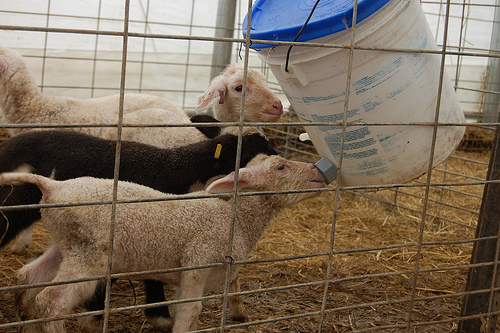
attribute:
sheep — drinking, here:
[0, 153, 328, 332]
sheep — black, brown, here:
[0, 113, 281, 252]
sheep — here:
[195, 64, 285, 141]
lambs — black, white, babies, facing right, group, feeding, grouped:
[0, 46, 326, 333]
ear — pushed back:
[204, 167, 256, 200]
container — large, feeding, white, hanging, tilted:
[242, 1, 467, 198]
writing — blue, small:
[289, 38, 427, 180]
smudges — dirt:
[339, 119, 466, 193]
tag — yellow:
[213, 142, 224, 160]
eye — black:
[275, 163, 286, 173]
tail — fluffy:
[0, 170, 52, 192]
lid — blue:
[242, 0, 391, 52]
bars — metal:
[1, 2, 499, 333]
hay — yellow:
[280, 209, 448, 290]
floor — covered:
[1, 152, 499, 332]